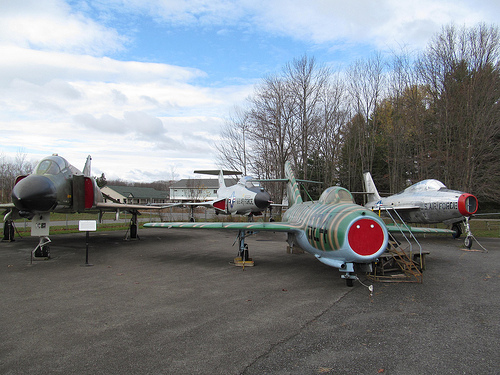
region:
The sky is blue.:
[6, 2, 481, 172]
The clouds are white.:
[4, 5, 227, 178]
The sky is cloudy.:
[5, 1, 486, 163]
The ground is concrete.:
[12, 216, 498, 364]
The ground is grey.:
[6, 218, 492, 371]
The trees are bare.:
[247, 52, 479, 203]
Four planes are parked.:
[15, 125, 489, 301]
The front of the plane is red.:
[346, 217, 381, 259]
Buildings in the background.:
[96, 162, 240, 222]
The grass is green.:
[10, 201, 142, 244]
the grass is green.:
[0, 200, 142, 237]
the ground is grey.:
[17, 221, 489, 364]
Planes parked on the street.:
[8, 125, 480, 305]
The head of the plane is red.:
[341, 210, 396, 268]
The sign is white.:
[72, 212, 98, 236]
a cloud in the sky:
[73, 100, 185, 146]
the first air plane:
[8, 138, 140, 258]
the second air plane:
[113, 150, 295, 238]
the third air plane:
[132, 143, 472, 293]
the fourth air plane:
[343, 130, 479, 255]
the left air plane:
[7, 144, 159, 279]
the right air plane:
[328, 150, 498, 258]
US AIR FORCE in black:
[418, 197, 459, 214]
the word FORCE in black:
[434, 196, 463, 213]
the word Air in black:
[424, 199, 440, 211]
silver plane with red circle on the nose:
[352, 170, 478, 250]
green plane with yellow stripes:
[140, 160, 456, 285]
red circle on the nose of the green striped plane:
[348, 215, 384, 255]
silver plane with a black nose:
[145, 170, 288, 219]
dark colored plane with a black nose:
[0, 153, 180, 260]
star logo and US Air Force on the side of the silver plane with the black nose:
[227, 191, 253, 206]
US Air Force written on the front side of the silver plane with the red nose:
[421, 202, 457, 211]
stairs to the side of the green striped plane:
[369, 202, 428, 281]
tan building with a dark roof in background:
[99, 184, 169, 206]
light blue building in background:
[165, 178, 238, 205]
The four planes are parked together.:
[16, 133, 486, 270]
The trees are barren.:
[212, 41, 359, 163]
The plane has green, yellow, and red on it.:
[161, 162, 409, 292]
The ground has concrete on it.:
[32, 277, 317, 368]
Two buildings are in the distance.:
[100, 176, 216, 198]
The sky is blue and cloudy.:
[56, 5, 232, 87]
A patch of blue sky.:
[155, 32, 231, 53]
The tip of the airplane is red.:
[341, 210, 388, 263]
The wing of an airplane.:
[122, 201, 299, 248]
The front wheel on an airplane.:
[458, 231, 475, 251]